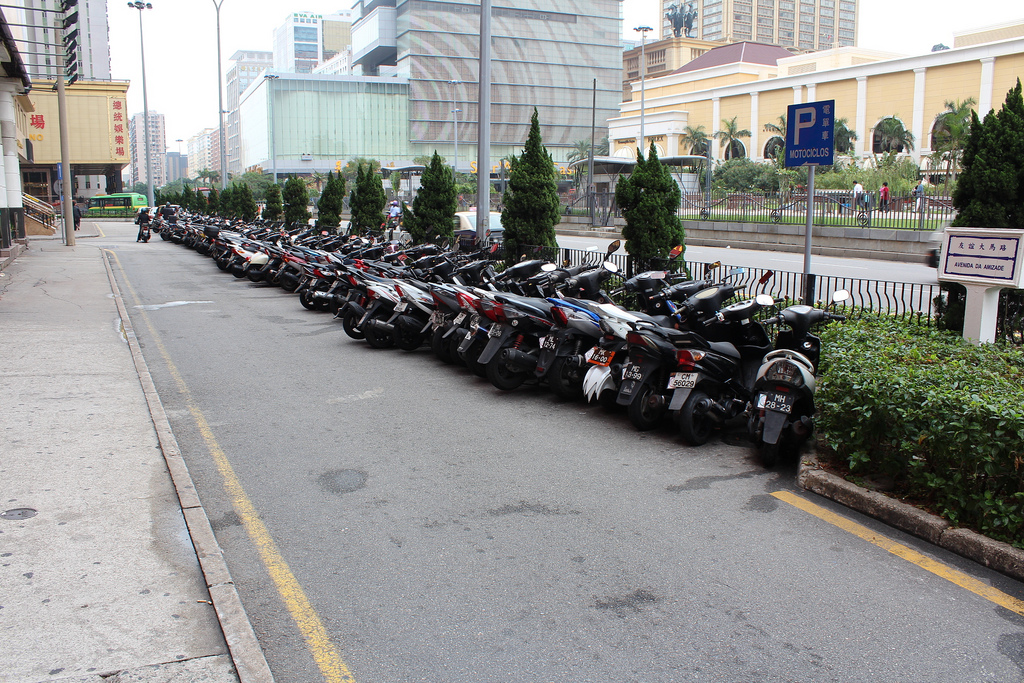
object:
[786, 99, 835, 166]
sign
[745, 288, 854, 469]
bike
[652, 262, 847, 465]
bike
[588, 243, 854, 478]
bike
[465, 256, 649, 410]
bike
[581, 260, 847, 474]
spots